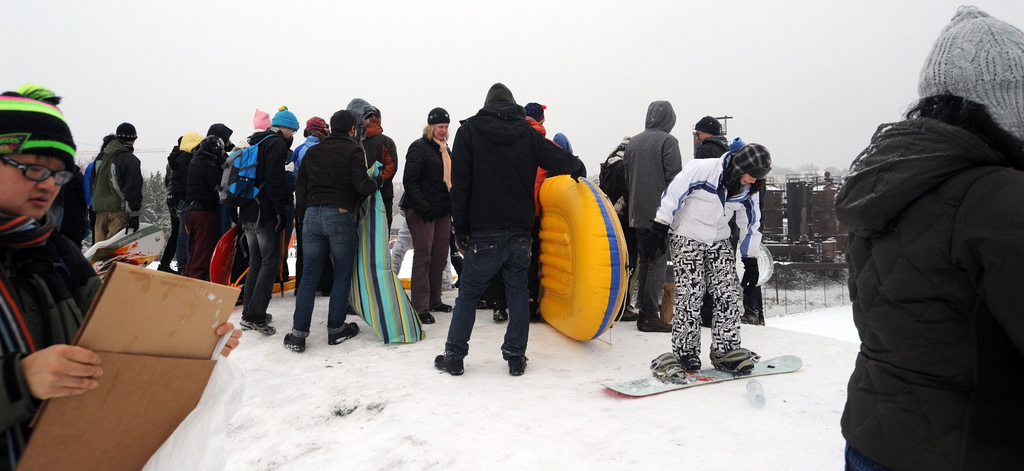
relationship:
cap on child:
[248, 94, 291, 134] [230, 112, 303, 223]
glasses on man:
[0, 156, 74, 192] [5, 87, 237, 462]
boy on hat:
[647, 144, 775, 379] [687, 106, 812, 217]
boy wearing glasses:
[2, 83, 243, 466] [8, 150, 78, 188]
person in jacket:
[832, 9, 1020, 466] [849, 114, 1008, 466]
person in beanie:
[832, 9, 1020, 466] [915, 4, 1021, 140]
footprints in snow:
[290, 373, 415, 465] [215, 327, 833, 465]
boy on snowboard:
[648, 144, 769, 376] [599, 352, 802, 398]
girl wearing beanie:
[832, 6, 1022, 468] [916, 4, 1022, 140]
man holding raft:
[429, 77, 560, 378] [539, 162, 641, 349]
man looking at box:
[5, 87, 237, 462] [22, 259, 239, 467]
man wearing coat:
[621, 96, 683, 331] [624, 90, 675, 233]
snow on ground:
[144, 266, 869, 467] [54, 262, 927, 464]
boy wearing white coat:
[647, 144, 775, 379] [631, 137, 768, 261]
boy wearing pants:
[647, 144, 775, 379] [664, 231, 760, 369]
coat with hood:
[624, 99, 681, 228] [634, 87, 680, 136]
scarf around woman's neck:
[424, 131, 457, 198] [420, 128, 450, 149]